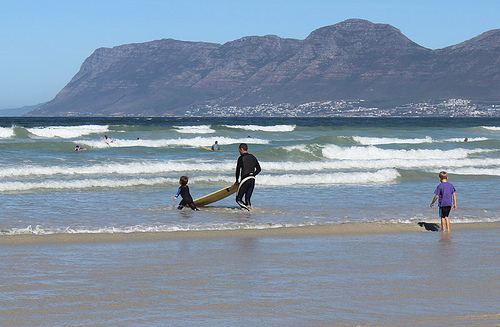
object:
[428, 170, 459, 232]
child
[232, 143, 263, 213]
man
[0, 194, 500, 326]
beach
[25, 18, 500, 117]
mountains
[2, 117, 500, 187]
water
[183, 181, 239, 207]
surfboard